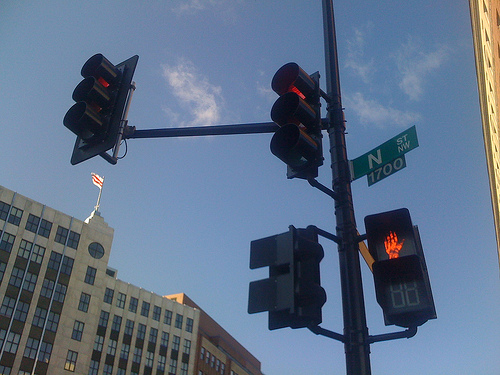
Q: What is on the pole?
A: Traffic lights.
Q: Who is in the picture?
A: Nobody.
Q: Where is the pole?
A: Next to the building.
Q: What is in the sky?
A: A cloud.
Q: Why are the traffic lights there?
A: To direct traffic.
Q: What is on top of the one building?
A: A flag.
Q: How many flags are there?
A: One.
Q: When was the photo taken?
A: During the day.